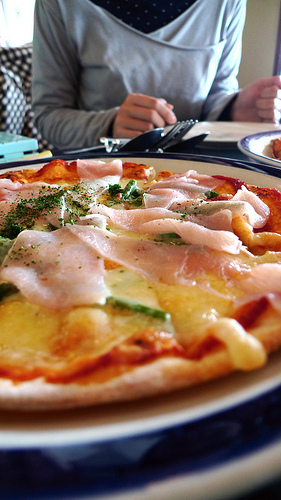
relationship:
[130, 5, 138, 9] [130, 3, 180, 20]
dot on shirt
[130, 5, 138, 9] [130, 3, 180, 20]
dot on top of shirt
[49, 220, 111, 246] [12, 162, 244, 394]
ham on top of pizza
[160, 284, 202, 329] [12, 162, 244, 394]
pineapple on top of pizza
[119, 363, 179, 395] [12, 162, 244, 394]
crust of pizza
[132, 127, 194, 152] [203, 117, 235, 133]
fork on top of table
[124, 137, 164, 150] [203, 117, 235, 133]
spoon on top of table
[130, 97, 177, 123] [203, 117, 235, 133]
fingers on table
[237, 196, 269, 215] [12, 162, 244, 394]
sauce on top of pizza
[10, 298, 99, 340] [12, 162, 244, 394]
cheese on top of pizza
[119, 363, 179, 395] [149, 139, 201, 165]
crust on top of plate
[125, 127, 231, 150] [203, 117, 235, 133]
utensils on top of table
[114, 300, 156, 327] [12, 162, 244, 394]
herbs on top of pizza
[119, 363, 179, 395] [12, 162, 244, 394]
crust attached to pizza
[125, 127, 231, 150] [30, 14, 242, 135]
utensils in front of woman